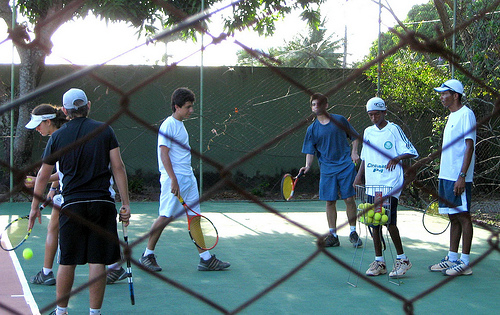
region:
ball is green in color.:
[21, 237, 41, 262]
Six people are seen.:
[16, 96, 46, 142]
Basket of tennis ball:
[342, 178, 417, 235]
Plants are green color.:
[393, 68, 433, 91]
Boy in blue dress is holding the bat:
[311, 117, 356, 205]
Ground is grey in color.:
[222, 218, 272, 272]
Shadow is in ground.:
[231, 216, 266, 276]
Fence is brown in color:
[288, 213, 384, 293]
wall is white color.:
[219, 76, 255, 99]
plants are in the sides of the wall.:
[219, 164, 299, 204]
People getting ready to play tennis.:
[143, 63, 495, 288]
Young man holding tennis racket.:
[168, 180, 226, 253]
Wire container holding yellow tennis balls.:
[348, 178, 400, 289]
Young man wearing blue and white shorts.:
[434, 170, 481, 220]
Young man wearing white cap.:
[427, 76, 471, 99]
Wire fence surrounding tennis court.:
[77, 78, 488, 314]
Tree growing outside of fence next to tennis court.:
[8, 3, 187, 192]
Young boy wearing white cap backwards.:
[363, 94, 392, 115]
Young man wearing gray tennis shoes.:
[138, 247, 235, 277]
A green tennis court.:
[228, 201, 330, 314]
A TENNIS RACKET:
[256, 167, 323, 206]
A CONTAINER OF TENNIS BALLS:
[344, 178, 401, 237]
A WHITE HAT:
[430, 78, 472, 99]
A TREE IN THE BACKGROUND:
[6, 8, 222, 187]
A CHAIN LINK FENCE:
[116, 90, 336, 307]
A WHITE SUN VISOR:
[20, 106, 65, 138]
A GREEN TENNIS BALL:
[14, 244, 45, 268]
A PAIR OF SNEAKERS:
[426, 251, 478, 282]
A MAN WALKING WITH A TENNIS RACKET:
[134, 82, 236, 281]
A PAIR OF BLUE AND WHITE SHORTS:
[434, 175, 481, 220]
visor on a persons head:
[21, 101, 62, 141]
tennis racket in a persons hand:
[166, 172, 225, 257]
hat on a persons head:
[56, 84, 96, 125]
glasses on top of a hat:
[428, 71, 473, 113]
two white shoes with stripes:
[425, 244, 478, 284]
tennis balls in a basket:
[351, 177, 398, 237]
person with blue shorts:
[301, 88, 364, 213]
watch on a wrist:
[456, 168, 471, 183]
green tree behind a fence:
[279, 20, 352, 97]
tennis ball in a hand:
[18, 172, 40, 193]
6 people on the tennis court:
[17, 62, 487, 280]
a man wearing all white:
[136, 85, 234, 274]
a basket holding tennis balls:
[353, 181, 408, 295]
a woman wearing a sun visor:
[18, 103, 59, 135]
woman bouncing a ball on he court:
[4, 99, 69, 303]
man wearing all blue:
[300, 86, 365, 226]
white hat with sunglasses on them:
[427, 77, 469, 111]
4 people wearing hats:
[8, 66, 474, 141]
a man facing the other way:
[24, 82, 145, 306]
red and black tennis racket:
[169, 188, 221, 253]